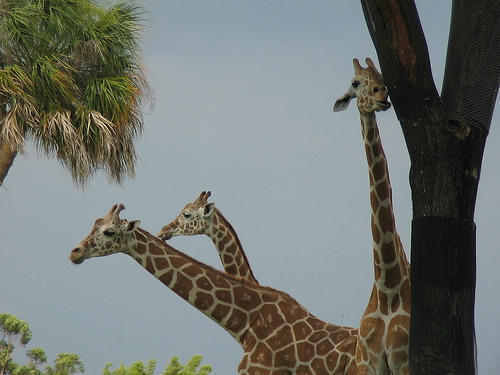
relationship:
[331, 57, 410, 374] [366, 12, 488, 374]
giraffe standing next to tree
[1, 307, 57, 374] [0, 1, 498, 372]
leaves of trees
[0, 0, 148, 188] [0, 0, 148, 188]
leaves on leaves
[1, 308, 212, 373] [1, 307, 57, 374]
leaves on leaves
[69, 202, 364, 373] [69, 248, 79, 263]
giraffe has brown nose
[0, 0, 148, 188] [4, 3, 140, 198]
leaves on a tree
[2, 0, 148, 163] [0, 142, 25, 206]
leaves on a tree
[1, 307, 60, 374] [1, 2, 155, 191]
leaves on a tree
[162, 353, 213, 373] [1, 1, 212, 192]
leaves on a tree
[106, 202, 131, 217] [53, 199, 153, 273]
ossicones on top of head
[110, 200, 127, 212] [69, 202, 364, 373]
ear on giraffe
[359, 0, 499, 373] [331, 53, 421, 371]
trunk by giraffe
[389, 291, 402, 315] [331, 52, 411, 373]
brown spot on giraffe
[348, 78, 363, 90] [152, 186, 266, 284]
eye on giraffe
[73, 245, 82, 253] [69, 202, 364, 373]
nostrils on giraffe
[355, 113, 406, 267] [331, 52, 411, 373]
neck on giraffe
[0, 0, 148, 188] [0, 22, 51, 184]
leaves on tree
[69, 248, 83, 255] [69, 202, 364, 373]
brown nose on giraffe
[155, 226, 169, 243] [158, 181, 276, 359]
nose on giraffe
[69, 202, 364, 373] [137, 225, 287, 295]
giraffe has mane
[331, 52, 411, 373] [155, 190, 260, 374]
giraffe standing next to giraffe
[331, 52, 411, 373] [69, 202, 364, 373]
giraffe standing next to giraffe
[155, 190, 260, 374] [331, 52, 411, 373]
giraffe standing next to giraffe